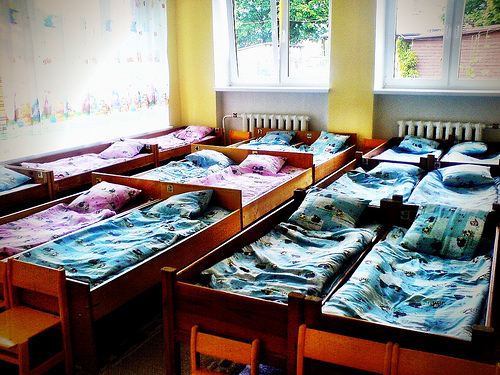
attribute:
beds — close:
[161, 188, 500, 374]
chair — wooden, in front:
[1, 256, 75, 375]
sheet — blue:
[13, 207, 214, 286]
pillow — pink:
[66, 178, 144, 212]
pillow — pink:
[237, 152, 289, 174]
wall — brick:
[410, 30, 499, 84]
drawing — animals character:
[13, 99, 41, 130]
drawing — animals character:
[41, 13, 58, 29]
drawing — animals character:
[142, 88, 169, 109]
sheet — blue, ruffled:
[191, 220, 375, 305]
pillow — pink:
[172, 124, 216, 141]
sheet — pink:
[1, 201, 117, 258]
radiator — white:
[221, 113, 313, 142]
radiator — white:
[394, 119, 500, 146]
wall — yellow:
[165, 0, 377, 143]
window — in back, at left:
[221, 1, 330, 89]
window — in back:
[384, 2, 500, 94]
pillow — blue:
[150, 188, 215, 220]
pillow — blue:
[285, 184, 373, 231]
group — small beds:
[2, 122, 499, 366]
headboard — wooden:
[160, 181, 242, 217]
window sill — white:
[217, 83, 333, 97]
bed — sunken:
[159, 188, 389, 364]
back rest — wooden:
[7, 258, 64, 299]